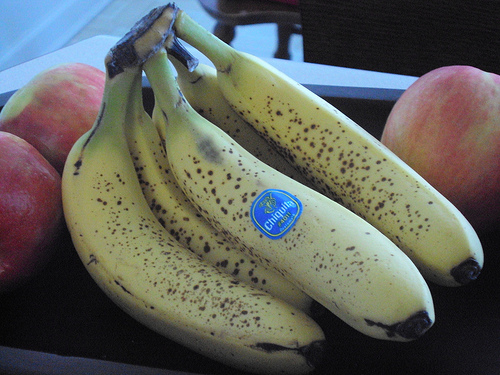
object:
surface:
[1, 70, 498, 374]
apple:
[386, 32, 488, 179]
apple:
[2, 32, 97, 132]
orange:
[380, 62, 497, 228]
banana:
[66, 0, 498, 375]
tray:
[1, 75, 498, 372]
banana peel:
[287, 222, 375, 285]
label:
[241, 189, 312, 243]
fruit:
[66, 52, 435, 329]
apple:
[0, 130, 63, 287]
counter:
[31, 27, 448, 94]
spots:
[71, 116, 372, 300]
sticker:
[249, 189, 301, 239]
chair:
[195, 1, 309, 61]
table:
[292, 0, 499, 78]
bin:
[4, 31, 478, 368]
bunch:
[71, 3, 481, 373]